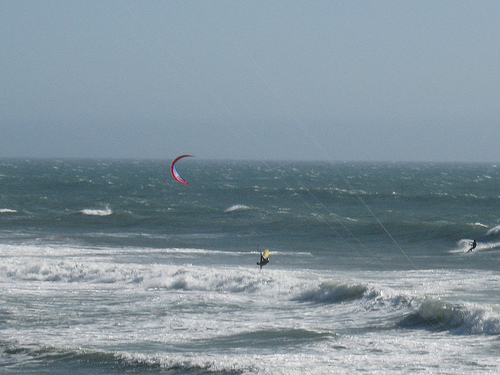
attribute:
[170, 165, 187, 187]
kite — c shaped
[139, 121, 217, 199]
kite — red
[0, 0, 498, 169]
sky — clear, hazy, gray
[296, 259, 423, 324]
wave — large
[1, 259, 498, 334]
wave — small 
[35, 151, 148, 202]
white caps — White 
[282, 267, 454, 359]
wave — big, white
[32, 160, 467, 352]
ocean — blue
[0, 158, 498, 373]
water — ocean , white